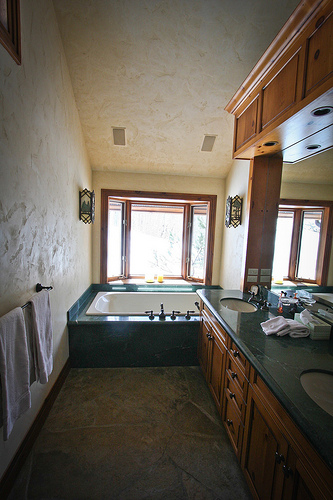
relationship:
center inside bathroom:
[196, 285, 333, 500] [4, 1, 331, 493]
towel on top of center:
[296, 305, 329, 342] [196, 285, 333, 500]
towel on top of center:
[279, 316, 306, 344] [196, 285, 333, 500]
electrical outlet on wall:
[245, 269, 257, 285] [244, 158, 285, 291]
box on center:
[294, 309, 332, 338] [196, 285, 333, 500]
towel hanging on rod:
[25, 287, 55, 389] [0, 281, 56, 320]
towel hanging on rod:
[0, 304, 36, 441] [0, 281, 56, 320]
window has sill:
[99, 192, 220, 287] [111, 274, 202, 287]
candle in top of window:
[144, 271, 158, 286] [99, 192, 220, 287]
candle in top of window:
[156, 271, 169, 290] [99, 192, 220, 287]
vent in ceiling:
[312, 108, 331, 120] [236, 87, 326, 171]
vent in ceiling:
[261, 135, 276, 153] [236, 87, 326, 171]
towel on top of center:
[260, 316, 311, 339] [196, 285, 333, 500]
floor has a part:
[6, 362, 254, 498] [84, 365, 179, 449]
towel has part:
[0, 304, 36, 441] [14, 314, 25, 400]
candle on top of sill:
[144, 271, 158, 286] [111, 274, 202, 287]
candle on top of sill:
[156, 271, 169, 290] [111, 274, 202, 287]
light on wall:
[78, 184, 97, 228] [6, 0, 99, 491]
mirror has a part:
[267, 149, 327, 318] [299, 189, 318, 248]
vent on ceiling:
[312, 108, 331, 120] [236, 87, 326, 171]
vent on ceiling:
[261, 135, 276, 153] [236, 87, 326, 171]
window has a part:
[99, 192, 220, 287] [133, 211, 176, 253]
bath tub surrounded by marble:
[86, 287, 202, 319] [66, 281, 206, 369]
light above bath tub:
[78, 184, 97, 228] [86, 287, 202, 319]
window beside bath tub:
[99, 192, 220, 287] [86, 287, 202, 319]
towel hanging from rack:
[25, 287, 55, 389] [0, 281, 56, 320]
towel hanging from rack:
[0, 304, 36, 441] [0, 281, 56, 320]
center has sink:
[196, 285, 333, 500] [220, 294, 261, 318]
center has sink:
[196, 285, 333, 500] [296, 370, 328, 416]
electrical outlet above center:
[245, 269, 257, 285] [196, 285, 333, 500]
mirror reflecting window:
[267, 149, 327, 318] [266, 199, 333, 297]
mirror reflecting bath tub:
[267, 149, 327, 318] [288, 287, 328, 323]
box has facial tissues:
[294, 309, 332, 338] [302, 312, 323, 328]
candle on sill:
[144, 271, 158, 286] [111, 274, 202, 287]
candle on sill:
[156, 271, 169, 290] [111, 274, 202, 287]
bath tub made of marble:
[86, 287, 202, 319] [66, 281, 206, 369]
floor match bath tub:
[6, 362, 254, 498] [86, 287, 202, 319]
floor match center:
[6, 362, 254, 498] [196, 285, 333, 500]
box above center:
[294, 309, 332, 338] [196, 285, 333, 500]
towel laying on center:
[260, 316, 311, 339] [196, 285, 333, 500]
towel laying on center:
[279, 316, 306, 344] [196, 285, 333, 500]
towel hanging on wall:
[25, 287, 55, 389] [6, 0, 99, 491]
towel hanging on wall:
[0, 304, 36, 441] [6, 0, 99, 491]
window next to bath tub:
[99, 192, 220, 287] [86, 287, 202, 319]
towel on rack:
[25, 287, 55, 389] [0, 281, 56, 320]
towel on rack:
[0, 304, 36, 441] [0, 281, 56, 320]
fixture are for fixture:
[33, 283, 59, 297] [36, 283, 53, 293]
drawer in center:
[222, 342, 250, 383] [214, 295, 330, 455]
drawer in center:
[222, 367, 245, 401] [214, 295, 330, 455]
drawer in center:
[220, 385, 245, 425] [214, 295, 330, 455]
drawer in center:
[220, 412, 241, 443] [214, 295, 330, 455]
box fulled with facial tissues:
[294, 309, 332, 338] [302, 312, 323, 328]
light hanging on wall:
[78, 184, 97, 228] [6, 0, 99, 491]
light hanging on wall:
[224, 196, 245, 234] [216, 155, 245, 294]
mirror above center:
[267, 149, 327, 318] [196, 285, 333, 500]